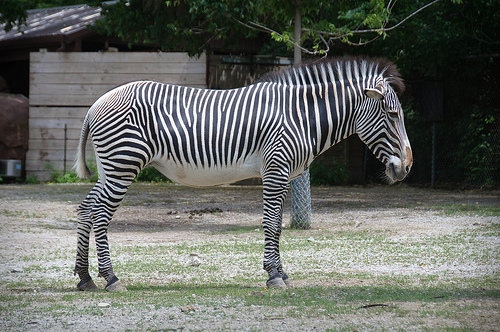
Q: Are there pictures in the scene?
A: No, there are no pictures.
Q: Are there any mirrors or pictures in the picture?
A: No, there are no pictures or mirrors.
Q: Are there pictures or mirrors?
A: No, there are no pictures or mirrors.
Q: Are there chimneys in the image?
A: No, there are no chimneys.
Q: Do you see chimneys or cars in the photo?
A: No, there are no chimneys or cars.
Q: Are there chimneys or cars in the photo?
A: No, there are no chimneys or cars.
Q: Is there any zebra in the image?
A: Yes, there is a zebra.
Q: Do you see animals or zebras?
A: Yes, there is a zebra.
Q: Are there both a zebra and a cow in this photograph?
A: No, there is a zebra but no cows.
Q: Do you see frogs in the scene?
A: No, there are no frogs.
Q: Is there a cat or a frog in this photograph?
A: No, there are no frogs or cats.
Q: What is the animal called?
A: The animal is a zebra.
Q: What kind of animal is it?
A: The animal is a zebra.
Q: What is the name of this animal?
A: This is a zebra.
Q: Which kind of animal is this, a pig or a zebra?
A: This is a zebra.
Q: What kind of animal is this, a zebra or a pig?
A: This is a zebra.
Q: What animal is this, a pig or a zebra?
A: This is a zebra.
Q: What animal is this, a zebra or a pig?
A: This is a zebra.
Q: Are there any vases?
A: No, there are no vases.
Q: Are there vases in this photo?
A: No, there are no vases.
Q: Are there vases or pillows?
A: No, there are no vases or pillows.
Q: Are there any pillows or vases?
A: No, there are no vases or pillows.